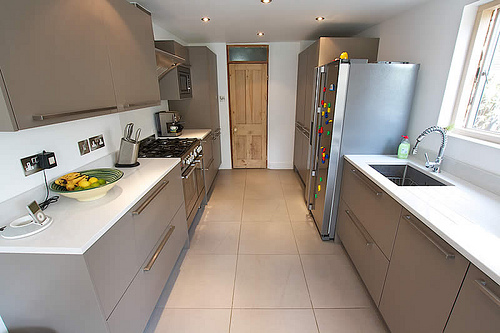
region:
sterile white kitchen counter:
[340, 125, 499, 301]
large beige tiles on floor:
[203, 192, 333, 329]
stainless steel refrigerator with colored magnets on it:
[307, 57, 409, 255]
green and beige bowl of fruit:
[50, 164, 126, 204]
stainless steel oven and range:
[135, 131, 217, 228]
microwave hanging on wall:
[153, 60, 206, 107]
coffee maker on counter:
[150, 101, 187, 143]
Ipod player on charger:
[4, 191, 53, 243]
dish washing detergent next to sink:
[392, 127, 412, 162]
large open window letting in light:
[437, 10, 498, 136]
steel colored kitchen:
[11, 12, 486, 331]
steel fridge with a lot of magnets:
[298, 54, 435, 251]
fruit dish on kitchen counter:
[31, 140, 134, 220]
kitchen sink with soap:
[346, 86, 486, 242]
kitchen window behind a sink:
[370, 33, 498, 209]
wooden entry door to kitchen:
[126, 10, 367, 306]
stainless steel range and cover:
[125, 39, 227, 238]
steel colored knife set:
[106, 119, 163, 177]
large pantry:
[273, 32, 340, 209]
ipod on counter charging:
[0, 127, 100, 332]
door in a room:
[221, 41, 277, 183]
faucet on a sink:
[406, 118, 456, 181]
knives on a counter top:
[107, 118, 154, 173]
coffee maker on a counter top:
[149, 104, 186, 141]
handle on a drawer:
[136, 219, 181, 285]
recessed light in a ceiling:
[192, 11, 217, 31]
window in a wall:
[428, 3, 498, 155]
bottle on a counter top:
[393, 128, 415, 165]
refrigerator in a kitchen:
[296, 53, 428, 236]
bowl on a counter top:
[43, 163, 134, 210]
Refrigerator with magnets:
[305, 60, 420, 240]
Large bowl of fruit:
[46, 165, 117, 200]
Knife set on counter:
[112, 120, 142, 165]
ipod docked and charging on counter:
[0, 150, 55, 240]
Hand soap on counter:
[395, 130, 410, 155]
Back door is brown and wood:
[226, 61, 269, 170]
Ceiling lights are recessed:
[200, 0, 325, 37]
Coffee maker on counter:
[155, 110, 181, 135]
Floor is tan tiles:
[140, 170, 387, 331]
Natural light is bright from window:
[433, 0, 499, 150]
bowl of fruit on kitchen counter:
[48, 164, 126, 201]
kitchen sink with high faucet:
[375, 125, 462, 200]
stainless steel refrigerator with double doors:
[302, 56, 428, 246]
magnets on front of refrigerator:
[313, 70, 339, 220]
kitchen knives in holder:
[115, 120, 142, 169]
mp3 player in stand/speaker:
[2, 200, 59, 242]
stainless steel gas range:
[131, 131, 209, 231]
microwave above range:
[162, 63, 196, 103]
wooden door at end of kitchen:
[226, 60, 273, 173]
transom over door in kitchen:
[229, 42, 272, 65]